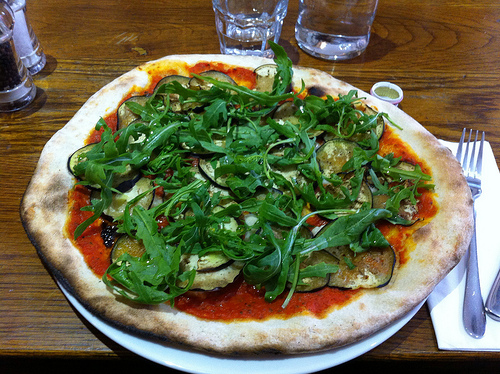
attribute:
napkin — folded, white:
[428, 134, 498, 346]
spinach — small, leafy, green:
[258, 37, 295, 98]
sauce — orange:
[216, 294, 270, 316]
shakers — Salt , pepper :
[0, 0, 71, 114]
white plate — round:
[59, 285, 431, 372]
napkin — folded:
[410, 127, 498, 352]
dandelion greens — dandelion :
[56, 35, 452, 312]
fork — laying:
[446, 116, 491, 345]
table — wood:
[1, 3, 496, 361]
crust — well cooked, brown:
[20, 52, 474, 359]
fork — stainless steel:
[451, 121, 498, 334]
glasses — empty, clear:
[216, 5, 378, 59]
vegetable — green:
[106, 64, 411, 294]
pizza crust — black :
[34, 52, 486, 370]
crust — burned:
[430, 127, 475, 257]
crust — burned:
[21, 122, 66, 281]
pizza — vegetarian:
[22, 38, 482, 368]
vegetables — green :
[61, 106, 442, 327]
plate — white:
[48, 282, 426, 372]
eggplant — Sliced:
[177, 257, 245, 296]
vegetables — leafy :
[78, 43, 425, 307]